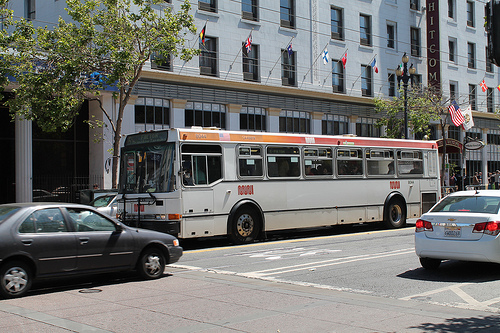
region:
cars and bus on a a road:
[30, 28, 495, 316]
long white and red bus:
[111, 117, 463, 234]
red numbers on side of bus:
[234, 180, 261, 197]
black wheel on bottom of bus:
[208, 205, 262, 237]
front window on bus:
[77, 128, 192, 190]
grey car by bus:
[72, 191, 190, 256]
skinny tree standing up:
[4, 7, 186, 195]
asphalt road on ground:
[255, 218, 405, 322]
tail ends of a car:
[404, 211, 498, 256]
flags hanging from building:
[182, 24, 410, 88]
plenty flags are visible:
[187, 12, 404, 97]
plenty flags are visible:
[181, 26, 337, 82]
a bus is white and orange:
[103, 115, 454, 250]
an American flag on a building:
[443, 87, 466, 138]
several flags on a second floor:
[183, 12, 490, 100]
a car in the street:
[3, 190, 188, 299]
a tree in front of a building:
[5, 6, 185, 192]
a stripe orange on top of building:
[159, 117, 450, 160]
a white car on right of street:
[403, 180, 499, 286]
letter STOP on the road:
[226, 230, 342, 267]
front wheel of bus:
[223, 186, 270, 250]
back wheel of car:
[373, 182, 413, 232]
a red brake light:
[452, 203, 472, 210]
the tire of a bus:
[225, 204, 262, 244]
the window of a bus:
[267, 143, 302, 175]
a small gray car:
[0, 201, 182, 295]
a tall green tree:
[0, 0, 203, 210]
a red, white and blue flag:
[242, 31, 254, 53]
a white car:
[412, 185, 497, 273]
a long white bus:
[114, 123, 445, 245]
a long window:
[245, 42, 265, 83]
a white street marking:
[398, 283, 485, 305]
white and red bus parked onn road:
[0, 36, 476, 306]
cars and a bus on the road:
[53, 70, 493, 297]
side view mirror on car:
[104, 209, 131, 239]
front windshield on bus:
[111, 147, 183, 196]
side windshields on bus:
[138, 111, 481, 190]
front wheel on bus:
[205, 188, 271, 263]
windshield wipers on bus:
[111, 136, 166, 213]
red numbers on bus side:
[237, 166, 249, 196]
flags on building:
[96, 55, 439, 123]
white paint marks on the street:
[168, 209, 378, 329]